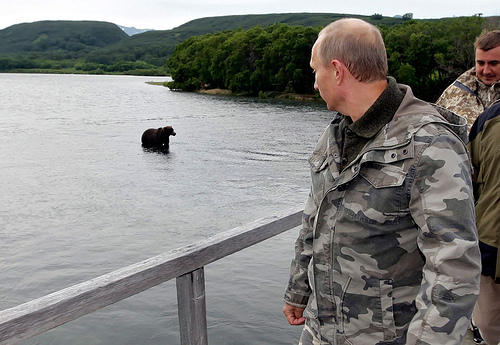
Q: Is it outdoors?
A: Yes, it is outdoors.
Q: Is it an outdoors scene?
A: Yes, it is outdoors.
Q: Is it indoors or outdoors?
A: It is outdoors.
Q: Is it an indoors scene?
A: No, it is outdoors.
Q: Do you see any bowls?
A: No, there are no bowls.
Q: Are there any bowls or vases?
A: No, there are no bowls or vases.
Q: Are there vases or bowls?
A: No, there are no bowls or vases.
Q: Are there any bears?
A: Yes, there is a bear.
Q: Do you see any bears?
A: Yes, there is a bear.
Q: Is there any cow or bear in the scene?
A: Yes, there is a bear.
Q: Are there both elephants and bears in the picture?
A: No, there is a bear but no elephants.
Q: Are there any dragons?
A: No, there are no dragons.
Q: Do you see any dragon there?
A: No, there are no dragons.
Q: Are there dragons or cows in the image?
A: No, there are no dragons or cows.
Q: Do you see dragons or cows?
A: No, there are no dragons or cows.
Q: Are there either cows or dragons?
A: No, there are no dragons or cows.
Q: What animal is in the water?
A: The bear is in the water.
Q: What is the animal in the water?
A: The animal is a bear.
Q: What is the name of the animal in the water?
A: The animal is a bear.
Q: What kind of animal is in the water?
A: The animal is a bear.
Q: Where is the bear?
A: The bear is in the water.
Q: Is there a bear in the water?
A: Yes, there is a bear in the water.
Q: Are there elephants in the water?
A: No, there is a bear in the water.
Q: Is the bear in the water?
A: Yes, the bear is in the water.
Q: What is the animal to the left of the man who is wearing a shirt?
A: The animal is a bear.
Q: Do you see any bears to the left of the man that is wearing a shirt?
A: Yes, there is a bear to the left of the man.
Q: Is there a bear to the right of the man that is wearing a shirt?
A: No, the bear is to the left of the man.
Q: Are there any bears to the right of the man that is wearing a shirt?
A: No, the bear is to the left of the man.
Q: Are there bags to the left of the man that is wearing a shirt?
A: No, there is a bear to the left of the man.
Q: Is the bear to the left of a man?
A: Yes, the bear is to the left of a man.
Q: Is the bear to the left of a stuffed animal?
A: No, the bear is to the left of a man.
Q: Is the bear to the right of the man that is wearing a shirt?
A: No, the bear is to the left of the man.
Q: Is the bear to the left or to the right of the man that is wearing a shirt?
A: The bear is to the left of the man.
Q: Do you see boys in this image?
A: No, there are no boys.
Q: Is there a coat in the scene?
A: Yes, there is a coat.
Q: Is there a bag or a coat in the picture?
A: Yes, there is a coat.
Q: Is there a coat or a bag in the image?
A: Yes, there is a coat.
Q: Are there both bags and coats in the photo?
A: No, there is a coat but no bags.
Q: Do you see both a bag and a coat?
A: No, there is a coat but no bags.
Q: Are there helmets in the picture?
A: No, there are no helmets.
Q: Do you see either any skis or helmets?
A: No, there are no helmets or skis.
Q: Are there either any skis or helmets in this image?
A: No, there are no helmets or skis.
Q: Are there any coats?
A: Yes, there is a coat.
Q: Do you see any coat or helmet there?
A: Yes, there is a coat.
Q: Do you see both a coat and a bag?
A: No, there is a coat but no bags.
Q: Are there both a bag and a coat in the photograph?
A: No, there is a coat but no bags.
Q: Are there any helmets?
A: No, there are no helmets.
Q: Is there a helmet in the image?
A: No, there are no helmets.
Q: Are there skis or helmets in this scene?
A: No, there are no helmets or skis.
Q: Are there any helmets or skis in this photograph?
A: No, there are no helmets or skis.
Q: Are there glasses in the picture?
A: No, there are no glasses.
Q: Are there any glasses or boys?
A: No, there are no glasses or boys.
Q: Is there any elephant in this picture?
A: No, there are no elephants.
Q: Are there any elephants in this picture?
A: No, there are no elephants.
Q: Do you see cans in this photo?
A: No, there are no cans.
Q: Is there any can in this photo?
A: No, there are no cans.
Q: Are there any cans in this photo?
A: No, there are no cans.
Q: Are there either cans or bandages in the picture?
A: No, there are no cans or bandages.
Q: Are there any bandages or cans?
A: No, there are no cans or bandages.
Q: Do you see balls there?
A: No, there are no balls.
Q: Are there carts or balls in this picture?
A: No, there are no balls or carts.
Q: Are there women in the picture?
A: No, there are no women.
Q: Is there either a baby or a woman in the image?
A: No, there are no women or babies.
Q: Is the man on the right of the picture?
A: Yes, the man is on the right of the image.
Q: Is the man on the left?
A: No, the man is on the right of the image.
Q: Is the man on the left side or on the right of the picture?
A: The man is on the right of the image.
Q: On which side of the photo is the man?
A: The man is on the right of the image.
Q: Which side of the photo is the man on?
A: The man is on the right of the image.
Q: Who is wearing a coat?
A: The man is wearing a coat.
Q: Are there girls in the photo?
A: No, there are no girls.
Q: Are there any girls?
A: No, there are no girls.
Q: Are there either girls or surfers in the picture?
A: No, there are no girls or surfers.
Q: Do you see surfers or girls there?
A: No, there are no girls or surfers.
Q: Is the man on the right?
A: Yes, the man is on the right of the image.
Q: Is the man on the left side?
A: No, the man is on the right of the image.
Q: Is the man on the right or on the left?
A: The man is on the right of the image.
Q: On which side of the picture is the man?
A: The man is on the right of the image.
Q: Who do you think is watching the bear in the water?
A: The man is watching the bear.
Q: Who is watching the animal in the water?
A: The man is watching the bear.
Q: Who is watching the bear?
A: The man is watching the bear.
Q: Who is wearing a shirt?
A: The man is wearing a shirt.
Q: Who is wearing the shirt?
A: The man is wearing a shirt.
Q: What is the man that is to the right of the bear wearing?
A: The man is wearing a shirt.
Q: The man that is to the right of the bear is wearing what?
A: The man is wearing a shirt.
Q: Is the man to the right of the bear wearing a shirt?
A: Yes, the man is wearing a shirt.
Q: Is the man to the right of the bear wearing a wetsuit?
A: No, the man is wearing a shirt.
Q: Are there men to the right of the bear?
A: Yes, there is a man to the right of the bear.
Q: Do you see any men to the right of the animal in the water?
A: Yes, there is a man to the right of the bear.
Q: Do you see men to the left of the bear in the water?
A: No, the man is to the right of the bear.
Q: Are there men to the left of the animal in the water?
A: No, the man is to the right of the bear.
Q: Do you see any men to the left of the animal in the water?
A: No, the man is to the right of the bear.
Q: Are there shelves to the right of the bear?
A: No, there is a man to the right of the bear.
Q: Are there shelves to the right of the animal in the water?
A: No, there is a man to the right of the bear.